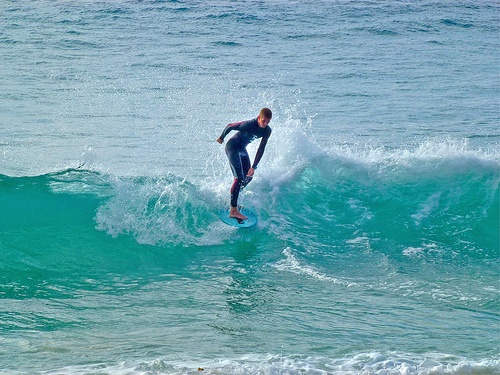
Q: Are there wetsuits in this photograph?
A: Yes, there is a wetsuit.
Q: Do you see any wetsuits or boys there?
A: Yes, there is a wetsuit.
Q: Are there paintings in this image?
A: No, there are no paintings.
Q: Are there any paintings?
A: No, there are no paintings.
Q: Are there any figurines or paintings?
A: No, there are no paintings or figurines.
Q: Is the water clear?
A: Yes, the water is clear.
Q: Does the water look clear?
A: Yes, the water is clear.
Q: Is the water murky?
A: No, the water is clear.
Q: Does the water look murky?
A: No, the water is clear.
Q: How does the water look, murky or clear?
A: The water is clear.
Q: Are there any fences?
A: No, there are no fences.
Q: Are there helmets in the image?
A: No, there are no helmets.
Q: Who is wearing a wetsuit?
A: The man is wearing a wetsuit.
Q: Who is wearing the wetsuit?
A: The man is wearing a wetsuit.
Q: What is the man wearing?
A: The man is wearing a wetsuit.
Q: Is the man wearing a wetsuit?
A: Yes, the man is wearing a wetsuit.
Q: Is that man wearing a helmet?
A: No, the man is wearing a wetsuit.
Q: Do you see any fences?
A: No, there are no fences.